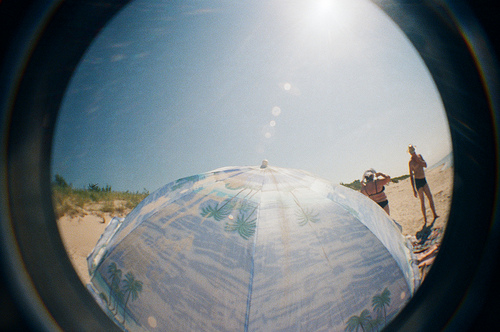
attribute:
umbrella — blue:
[86, 159, 421, 329]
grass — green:
[81, 190, 88, 200]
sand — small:
[58, 211, 98, 241]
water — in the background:
[427, 149, 452, 170]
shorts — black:
[413, 175, 428, 188]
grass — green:
[67, 188, 92, 217]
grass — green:
[55, 189, 138, 214]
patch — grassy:
[45, 187, 146, 217]